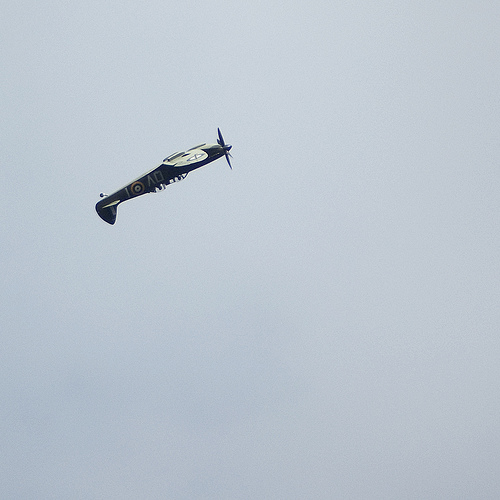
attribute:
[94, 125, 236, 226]
jet — here, blue, flying, white, upside down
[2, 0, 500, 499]
sky — here, gray, overcast, pale, clear, blue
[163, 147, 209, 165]
bottom — white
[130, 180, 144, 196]
target — drawn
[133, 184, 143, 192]
circle — white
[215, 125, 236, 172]
propeller — black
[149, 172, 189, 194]
cockpit — small, glass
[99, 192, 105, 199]
wheel — small, black, raised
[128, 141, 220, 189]
underbelly — white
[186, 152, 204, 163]
logo — small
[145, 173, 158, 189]
letter — white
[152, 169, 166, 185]
letter — white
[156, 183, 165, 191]
person — inside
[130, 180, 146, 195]
circle — yellow